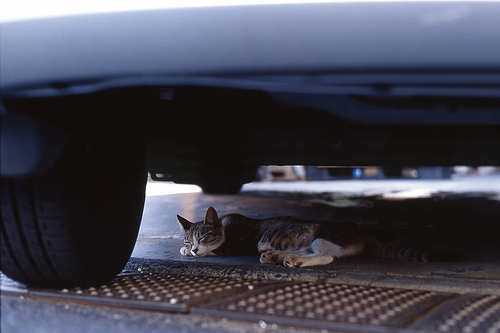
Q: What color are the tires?
A: Black.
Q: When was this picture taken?
A: Daytime.